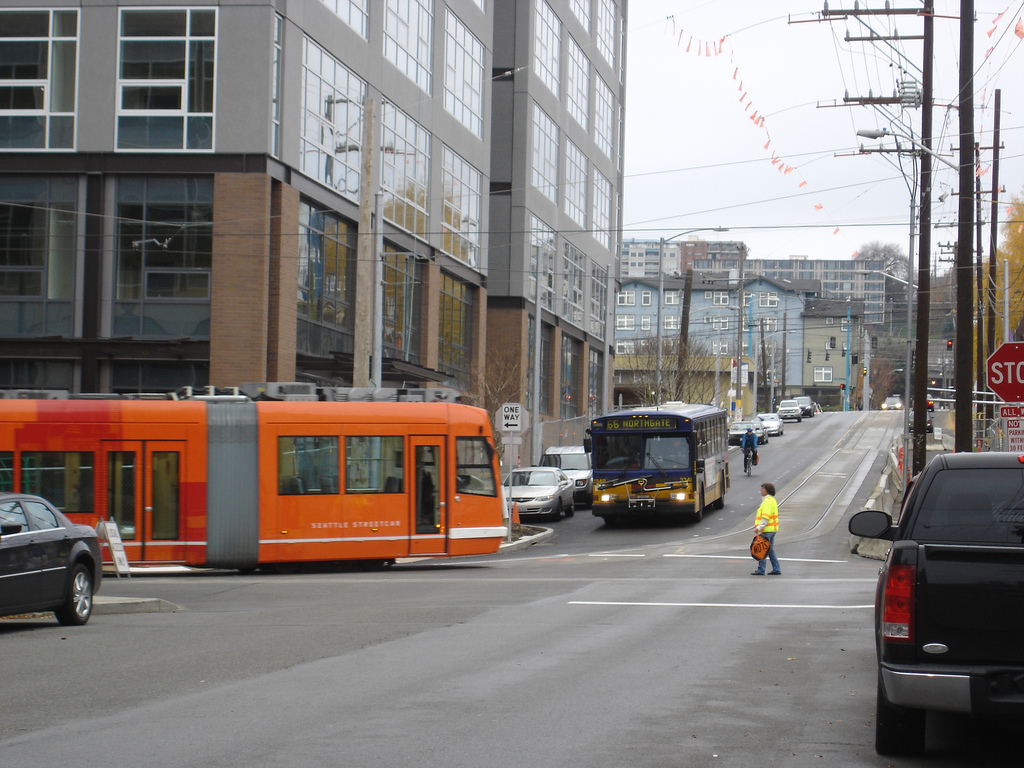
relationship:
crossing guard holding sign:
[750, 482, 782, 575] [750, 531, 770, 563]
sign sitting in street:
[99, 514, 132, 573] [6, 421, 881, 763]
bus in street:
[578, 401, 732, 530] [18, 502, 932, 756]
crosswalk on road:
[578, 535, 788, 621] [8, 503, 880, 750]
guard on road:
[741, 469, 788, 585] [8, 503, 880, 750]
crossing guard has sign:
[750, 482, 782, 575] [747, 526, 776, 560]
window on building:
[115, 81, 186, 119] [6, 8, 312, 386]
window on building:
[115, 9, 198, 35] [6, 8, 312, 386]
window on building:
[187, 5, 222, 37] [6, 8, 312, 386]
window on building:
[187, 108, 222, 157] [6, 8, 312, 386]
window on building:
[38, 34, 88, 115] [6, 8, 312, 386]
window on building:
[47, 4, 87, 44] [6, 8, 312, 386]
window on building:
[290, 182, 368, 364] [7, 3, 613, 485]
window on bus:
[282, 435, 345, 503] [3, 389, 516, 571]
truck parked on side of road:
[0, 402, 929, 765] [0, 409, 907, 767]